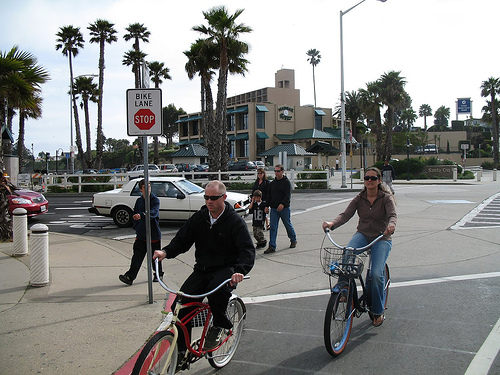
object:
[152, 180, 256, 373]
man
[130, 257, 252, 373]
bike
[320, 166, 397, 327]
woman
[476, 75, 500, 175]
palm trees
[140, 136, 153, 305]
pole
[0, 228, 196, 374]
sidewalk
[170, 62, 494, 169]
building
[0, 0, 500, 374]
city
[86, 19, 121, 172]
tree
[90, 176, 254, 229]
car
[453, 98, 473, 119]
billboard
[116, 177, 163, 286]
man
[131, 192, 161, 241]
sweater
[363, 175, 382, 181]
sunglasses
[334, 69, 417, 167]
tree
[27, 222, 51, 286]
column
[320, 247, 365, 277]
basket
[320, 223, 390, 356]
bicycle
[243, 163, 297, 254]
family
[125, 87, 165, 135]
sign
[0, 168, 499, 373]
road